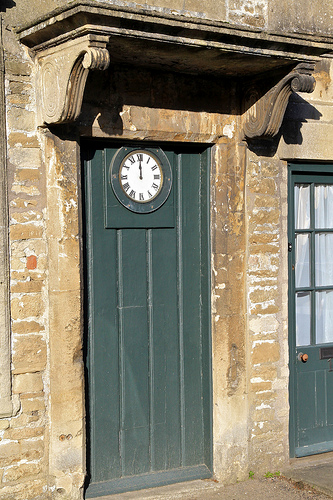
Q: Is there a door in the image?
A: Yes, there is a door.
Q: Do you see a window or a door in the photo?
A: Yes, there is a door.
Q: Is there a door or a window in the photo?
A: Yes, there is a door.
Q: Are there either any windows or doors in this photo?
A: Yes, there is a door.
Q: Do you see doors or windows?
A: Yes, there is a door.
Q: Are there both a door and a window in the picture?
A: Yes, there are both a door and a window.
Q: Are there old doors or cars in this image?
A: Yes, there is an old door.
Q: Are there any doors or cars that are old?
A: Yes, the door is old.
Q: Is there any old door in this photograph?
A: Yes, there is an old door.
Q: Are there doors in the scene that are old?
A: Yes, there is a door that is old.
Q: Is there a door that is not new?
A: Yes, there is a old door.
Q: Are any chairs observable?
A: No, there are no chairs.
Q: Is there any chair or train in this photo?
A: No, there are no chairs or trains.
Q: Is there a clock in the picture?
A: Yes, there is a clock.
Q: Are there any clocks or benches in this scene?
A: Yes, there is a clock.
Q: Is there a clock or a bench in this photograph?
A: Yes, there is a clock.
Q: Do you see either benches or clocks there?
A: Yes, there is a clock.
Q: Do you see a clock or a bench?
A: Yes, there is a clock.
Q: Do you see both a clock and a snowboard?
A: No, there is a clock but no snowboards.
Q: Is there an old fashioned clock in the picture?
A: Yes, there is an old fashioned clock.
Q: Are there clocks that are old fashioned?
A: Yes, there is a clock that is old fashioned.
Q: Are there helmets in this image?
A: No, there are no helmets.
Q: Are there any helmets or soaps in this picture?
A: No, there are no helmets or soaps.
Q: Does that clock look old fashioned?
A: Yes, the clock is old fashioned.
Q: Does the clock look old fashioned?
A: Yes, the clock is old fashioned.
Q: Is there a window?
A: Yes, there is a window.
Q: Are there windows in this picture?
A: Yes, there is a window.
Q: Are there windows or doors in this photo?
A: Yes, there is a window.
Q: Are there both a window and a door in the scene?
A: Yes, there are both a window and a door.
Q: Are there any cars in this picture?
A: No, there are no cars.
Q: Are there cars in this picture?
A: No, there are no cars.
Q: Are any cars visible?
A: No, there are no cars.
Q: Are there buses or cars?
A: No, there are no cars or buses.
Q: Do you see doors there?
A: Yes, there is a door.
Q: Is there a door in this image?
A: Yes, there is a door.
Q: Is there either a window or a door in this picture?
A: Yes, there is a door.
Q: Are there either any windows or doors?
A: Yes, there is a door.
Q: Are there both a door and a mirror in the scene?
A: No, there is a door but no mirrors.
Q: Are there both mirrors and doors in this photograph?
A: No, there is a door but no mirrors.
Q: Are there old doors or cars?
A: Yes, there is an old door.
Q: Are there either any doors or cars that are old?
A: Yes, the door is old.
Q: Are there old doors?
A: Yes, there is an old door.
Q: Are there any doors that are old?
A: Yes, there is a door that is old.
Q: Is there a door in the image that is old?
A: Yes, there is a door that is old.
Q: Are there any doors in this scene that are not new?
A: Yes, there is a old door.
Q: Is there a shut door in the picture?
A: Yes, there is a shut door.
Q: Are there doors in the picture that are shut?
A: Yes, there is a door that is shut.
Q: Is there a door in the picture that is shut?
A: Yes, there is a door that is shut.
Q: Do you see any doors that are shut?
A: Yes, there is a door that is shut.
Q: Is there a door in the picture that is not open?
A: Yes, there is an shut door.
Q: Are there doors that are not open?
A: Yes, there is an shut door.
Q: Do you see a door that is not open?
A: Yes, there is an shut door.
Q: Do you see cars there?
A: No, there are no cars.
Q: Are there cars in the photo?
A: No, there are no cars.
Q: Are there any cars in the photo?
A: No, there are no cars.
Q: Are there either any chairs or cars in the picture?
A: No, there are no cars or chairs.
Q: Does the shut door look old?
A: Yes, the door is old.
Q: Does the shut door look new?
A: No, the door is old.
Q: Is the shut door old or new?
A: The door is old.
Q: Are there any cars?
A: No, there are no cars.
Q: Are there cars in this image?
A: No, there are no cars.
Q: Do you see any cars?
A: No, there are no cars.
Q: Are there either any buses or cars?
A: No, there are no cars or buses.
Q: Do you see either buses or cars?
A: No, there are no cars or buses.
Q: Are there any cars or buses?
A: No, there are no cars or buses.